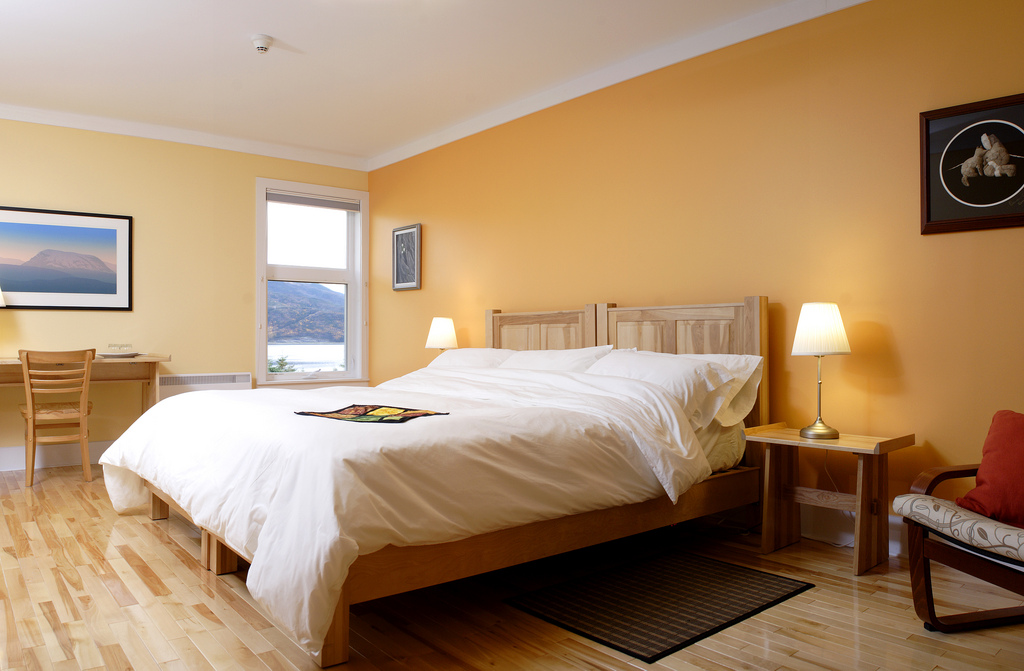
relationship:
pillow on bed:
[497, 338, 614, 386] [89, 279, 799, 635]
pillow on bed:
[581, 334, 762, 421] [89, 279, 799, 635]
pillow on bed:
[418, 334, 513, 388] [89, 279, 799, 635]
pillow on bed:
[581, 334, 762, 421] [54, 269, 814, 666]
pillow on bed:
[497, 331, 624, 385] [54, 269, 814, 666]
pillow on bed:
[417, 334, 519, 388] [54, 269, 814, 666]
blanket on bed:
[92, 328, 690, 505] [54, 269, 814, 666]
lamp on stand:
[781, 293, 867, 446] [727, 401, 922, 586]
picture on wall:
[0, 189, 142, 319] [356, 158, 1015, 336]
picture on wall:
[382, 218, 430, 296] [356, 158, 1015, 336]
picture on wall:
[910, 94, 1022, 247] [356, 158, 1015, 336]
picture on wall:
[383, 217, 434, 300] [356, 151, 1021, 450]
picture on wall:
[3, 189, 141, 319] [0, 104, 378, 444]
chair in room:
[888, 380, 1022, 631] [9, 20, 1018, 667]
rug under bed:
[496, 527, 841, 660] [88, 296, 863, 667]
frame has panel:
[79, 452, 782, 664] [600, 306, 681, 346]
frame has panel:
[79, 379, 794, 667] [619, 318, 741, 351]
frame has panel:
[79, 379, 794, 667] [612, 318, 663, 351]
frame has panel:
[79, 379, 794, 667] [695, 318, 737, 357]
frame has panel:
[79, 379, 794, 667] [635, 319, 659, 343]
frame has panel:
[79, 379, 794, 667] [620, 322, 639, 339]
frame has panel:
[79, 379, 794, 667] [541, 325, 567, 344]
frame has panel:
[79, 379, 794, 667] [677, 323, 701, 352]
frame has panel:
[79, 379, 794, 667] [538, 323, 552, 340]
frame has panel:
[79, 379, 794, 667] [516, 323, 535, 343]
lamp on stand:
[781, 280, 881, 449] [740, 401, 922, 579]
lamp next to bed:
[781, 280, 881, 449] [98, 292, 790, 668]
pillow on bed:
[497, 331, 624, 385] [105, 331, 785, 641]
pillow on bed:
[581, 334, 762, 421] [99, 322, 770, 608]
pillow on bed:
[417, 334, 519, 388] [141, 299, 759, 607]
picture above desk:
[383, 217, 434, 285] [0, 337, 171, 440]